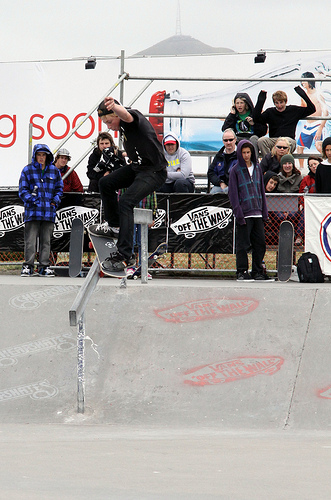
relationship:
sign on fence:
[170, 205, 233, 239] [280, 205, 288, 213]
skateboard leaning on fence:
[276, 219, 296, 281] [264, 193, 328, 274]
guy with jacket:
[227, 137, 284, 277] [230, 137, 264, 209]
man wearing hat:
[86, 97, 168, 273] [94, 97, 127, 110]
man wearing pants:
[86, 97, 168, 273] [97, 164, 168, 259]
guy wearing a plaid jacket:
[17, 143, 65, 279] [19, 143, 62, 220]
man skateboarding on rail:
[78, 97, 166, 273] [67, 198, 153, 415]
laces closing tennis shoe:
[94, 219, 108, 233] [87, 222, 118, 238]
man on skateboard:
[86, 97, 168, 273] [83, 219, 129, 277]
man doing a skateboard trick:
[86, 97, 168, 273] [88, 224, 182, 349]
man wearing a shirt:
[86, 97, 168, 273] [121, 118, 161, 169]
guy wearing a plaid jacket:
[17, 143, 65, 279] [14, 140, 67, 219]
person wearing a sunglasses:
[208, 123, 238, 195] [222, 137, 235, 142]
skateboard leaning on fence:
[276, 219, 296, 281] [153, 190, 325, 275]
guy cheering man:
[251, 86, 316, 141] [86, 97, 168, 273]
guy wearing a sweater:
[17, 143, 65, 279] [163, 128, 193, 183]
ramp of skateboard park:
[202, 285, 252, 319] [1, 60, 329, 497]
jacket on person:
[230, 136, 262, 173] [226, 137, 274, 280]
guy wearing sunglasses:
[227, 137, 276, 283] [222, 137, 235, 142]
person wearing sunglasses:
[205, 123, 237, 195] [222, 136, 236, 142]